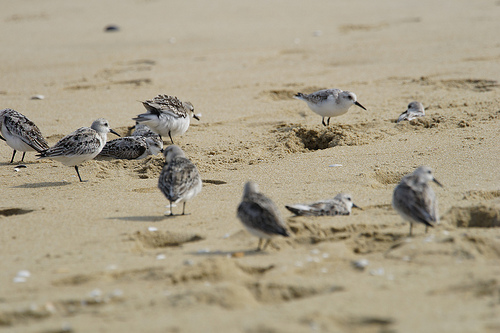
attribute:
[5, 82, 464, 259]
birds — grey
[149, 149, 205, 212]
bird — gray, grey, white, standing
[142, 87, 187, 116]
feathers — ruffled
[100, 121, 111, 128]
eye — black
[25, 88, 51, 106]
rock — small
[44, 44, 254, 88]
sand — brown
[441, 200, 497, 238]
whole — large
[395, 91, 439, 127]
seashell — small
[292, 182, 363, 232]
bird — basking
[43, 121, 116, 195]
bird — standing